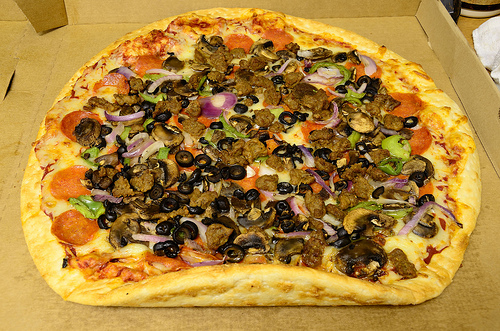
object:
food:
[21, 7, 483, 307]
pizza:
[22, 7, 483, 306]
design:
[20, 6, 482, 305]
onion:
[104, 110, 146, 122]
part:
[16, 0, 68, 34]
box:
[0, 1, 499, 329]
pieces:
[221, 31, 253, 50]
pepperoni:
[51, 208, 99, 245]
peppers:
[376, 157, 404, 174]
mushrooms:
[108, 211, 141, 248]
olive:
[176, 149, 193, 167]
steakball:
[128, 170, 152, 191]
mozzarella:
[42, 137, 70, 165]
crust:
[110, 263, 388, 305]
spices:
[189, 25, 221, 34]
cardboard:
[15, 0, 68, 33]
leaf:
[348, 200, 380, 210]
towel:
[470, 15, 499, 84]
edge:
[19, 186, 40, 221]